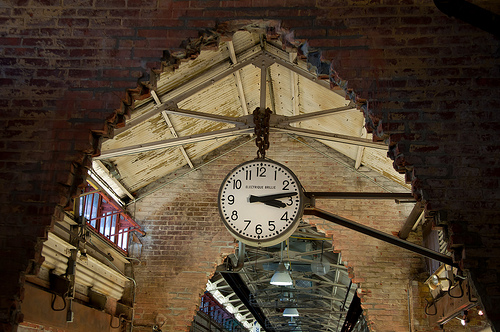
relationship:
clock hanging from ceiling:
[218, 157, 315, 249] [87, 21, 412, 209]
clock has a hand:
[218, 157, 315, 249] [250, 192, 298, 203]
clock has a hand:
[218, 157, 315, 249] [250, 195, 287, 208]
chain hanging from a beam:
[252, 106, 272, 158] [92, 49, 389, 161]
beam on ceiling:
[92, 49, 389, 161] [87, 21, 412, 209]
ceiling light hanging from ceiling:
[270, 241, 293, 286] [210, 218, 363, 331]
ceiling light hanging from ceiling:
[282, 308, 299, 317] [210, 218, 363, 331]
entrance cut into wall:
[16, 26, 492, 332] [0, 0, 499, 332]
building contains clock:
[0, 0, 499, 332] [218, 157, 315, 249]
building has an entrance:
[0, 0, 499, 332] [16, 26, 492, 332]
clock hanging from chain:
[218, 157, 315, 249] [252, 106, 272, 158]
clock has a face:
[218, 157, 315, 249] [220, 161, 299, 240]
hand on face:
[250, 192, 298, 203] [220, 161, 299, 240]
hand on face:
[250, 195, 287, 208] [220, 161, 299, 240]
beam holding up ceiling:
[92, 49, 389, 161] [87, 21, 412, 209]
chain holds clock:
[252, 106, 272, 158] [218, 157, 315, 249]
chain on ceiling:
[252, 106, 272, 158] [87, 21, 412, 209]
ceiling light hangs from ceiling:
[270, 241, 293, 286] [210, 218, 363, 331]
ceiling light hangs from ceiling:
[282, 308, 299, 317] [210, 218, 363, 331]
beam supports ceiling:
[92, 49, 389, 161] [87, 21, 412, 209]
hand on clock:
[250, 192, 298, 203] [218, 157, 315, 249]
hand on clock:
[250, 195, 287, 208] [218, 157, 315, 249]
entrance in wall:
[16, 26, 492, 332] [0, 0, 499, 332]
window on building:
[116, 214, 130, 253] [0, 0, 499, 332]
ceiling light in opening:
[270, 241, 293, 286] [189, 219, 370, 331]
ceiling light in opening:
[282, 308, 299, 317] [189, 219, 370, 331]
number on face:
[256, 166, 266, 177] [220, 161, 299, 240]